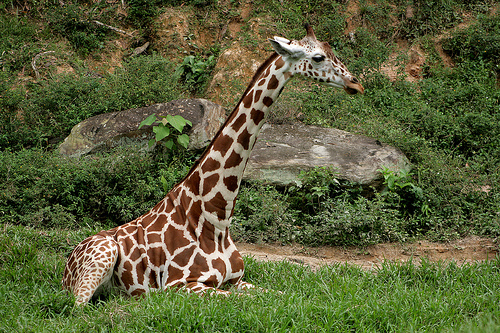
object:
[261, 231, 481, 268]
dirt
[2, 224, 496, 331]
grass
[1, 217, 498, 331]
field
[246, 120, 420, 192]
barren rock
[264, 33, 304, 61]
ear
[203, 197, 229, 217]
brown spot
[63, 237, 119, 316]
leg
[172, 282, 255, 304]
leg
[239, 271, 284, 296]
leg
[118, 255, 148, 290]
spots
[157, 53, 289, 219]
neck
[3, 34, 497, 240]
grass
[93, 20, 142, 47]
stick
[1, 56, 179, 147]
bushes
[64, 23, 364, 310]
animal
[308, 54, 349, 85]
brown spots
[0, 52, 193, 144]
trees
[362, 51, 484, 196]
bush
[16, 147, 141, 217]
bush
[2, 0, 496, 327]
ground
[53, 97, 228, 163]
rocks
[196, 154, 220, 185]
spot